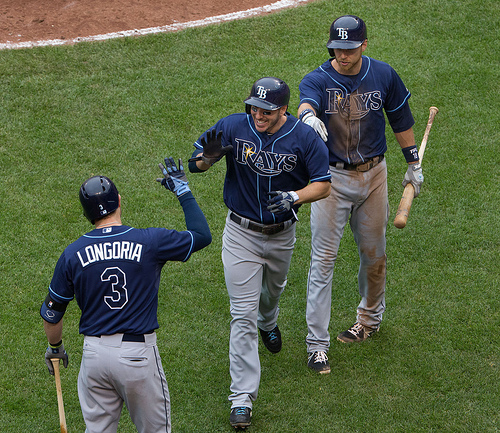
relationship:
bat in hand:
[365, 48, 451, 251] [398, 147, 446, 193]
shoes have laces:
[296, 293, 392, 382] [298, 326, 409, 386]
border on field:
[1, 0, 321, 91] [0, 0, 491, 217]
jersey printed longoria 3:
[290, 38, 435, 176] [310, 70, 404, 127]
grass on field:
[2, 0, 483, 63] [0, 0, 491, 217]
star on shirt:
[240, 145, 258, 162] [195, 102, 359, 226]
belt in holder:
[224, 202, 306, 246] [234, 201, 255, 236]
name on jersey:
[39, 217, 158, 265] [290, 38, 435, 176]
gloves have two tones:
[141, 149, 209, 210] [166, 169, 195, 196]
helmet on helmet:
[319, 8, 379, 50] [319, 8, 379, 50]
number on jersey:
[85, 260, 152, 314] [52, 217, 216, 339]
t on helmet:
[328, 22, 343, 36] [319, 8, 379, 50]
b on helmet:
[338, 27, 356, 44] [319, 8, 379, 50]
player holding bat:
[284, 8, 435, 369] [365, 48, 451, 251]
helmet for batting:
[319, 8, 379, 50] [383, 79, 462, 217]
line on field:
[1, 0, 321, 91] [0, 0, 491, 217]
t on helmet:
[335, 27, 344, 37] [319, 8, 379, 50]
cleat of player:
[307, 295, 406, 356] [284, 8, 435, 369]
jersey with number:
[290, 38, 435, 176] [85, 260, 152, 314]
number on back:
[85, 260, 152, 314] [75, 212, 169, 356]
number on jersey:
[85, 260, 152, 314] [290, 38, 435, 176]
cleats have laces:
[296, 293, 392, 382] [298, 326, 409, 386]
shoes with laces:
[296, 293, 392, 382] [298, 326, 409, 386]